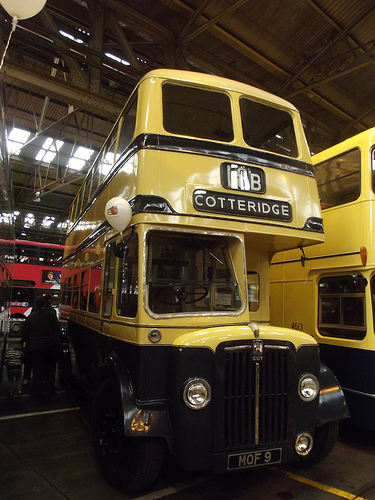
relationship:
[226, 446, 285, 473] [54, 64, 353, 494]
license plate on bus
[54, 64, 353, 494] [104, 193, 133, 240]
bus with balloon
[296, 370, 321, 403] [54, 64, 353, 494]
headlight on bus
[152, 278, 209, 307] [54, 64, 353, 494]
steering wheel on bus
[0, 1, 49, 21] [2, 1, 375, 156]
balloon near ceiling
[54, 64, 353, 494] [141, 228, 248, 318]
bus has windshield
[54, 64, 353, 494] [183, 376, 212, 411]
bus has headlight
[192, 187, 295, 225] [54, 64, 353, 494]
sign on bus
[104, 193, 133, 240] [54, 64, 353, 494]
balloon attached to bus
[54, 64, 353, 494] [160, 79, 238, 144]
bus has window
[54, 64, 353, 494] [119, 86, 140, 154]
bus has window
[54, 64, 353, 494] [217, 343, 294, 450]
bus has grill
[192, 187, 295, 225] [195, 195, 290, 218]
sign says cotteridge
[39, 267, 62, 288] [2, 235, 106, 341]
banner on bus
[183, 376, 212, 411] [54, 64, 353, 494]
headlight on bus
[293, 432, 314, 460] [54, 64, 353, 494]
light on bus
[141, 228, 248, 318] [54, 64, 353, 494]
front window on bus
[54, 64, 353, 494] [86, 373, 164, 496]
bus has wheel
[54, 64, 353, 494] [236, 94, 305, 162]
bus has window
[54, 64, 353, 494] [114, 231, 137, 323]
bus has window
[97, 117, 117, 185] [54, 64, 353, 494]
window on bus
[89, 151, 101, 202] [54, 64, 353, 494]
window on bus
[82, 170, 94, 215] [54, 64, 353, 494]
window on bus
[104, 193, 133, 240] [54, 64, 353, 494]
balloon on bus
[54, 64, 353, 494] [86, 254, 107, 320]
bus has window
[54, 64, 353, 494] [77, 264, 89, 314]
bus has window